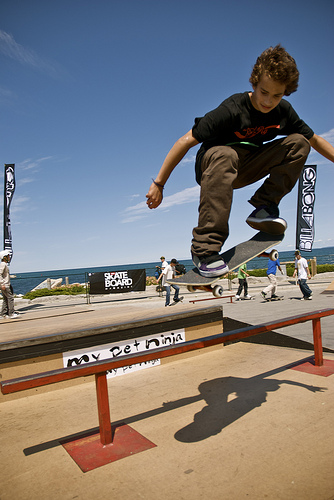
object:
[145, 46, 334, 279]
boy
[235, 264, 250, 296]
boy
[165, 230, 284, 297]
skatboard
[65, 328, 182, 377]
sign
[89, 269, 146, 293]
banner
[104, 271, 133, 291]
lettering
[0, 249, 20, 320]
kid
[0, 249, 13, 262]
helmet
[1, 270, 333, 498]
ground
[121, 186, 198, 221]
clouds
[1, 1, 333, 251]
sky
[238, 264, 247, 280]
shirt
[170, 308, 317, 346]
rail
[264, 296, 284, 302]
skateboarder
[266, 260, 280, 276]
blue shirt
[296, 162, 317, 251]
flag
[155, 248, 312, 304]
people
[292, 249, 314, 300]
boy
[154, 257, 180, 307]
boy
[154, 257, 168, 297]
boy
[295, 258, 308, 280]
t-shirt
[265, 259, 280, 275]
t-shirt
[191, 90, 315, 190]
black tshirt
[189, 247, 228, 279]
shoe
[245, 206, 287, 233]
shoe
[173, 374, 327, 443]
reflection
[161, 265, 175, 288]
shirt